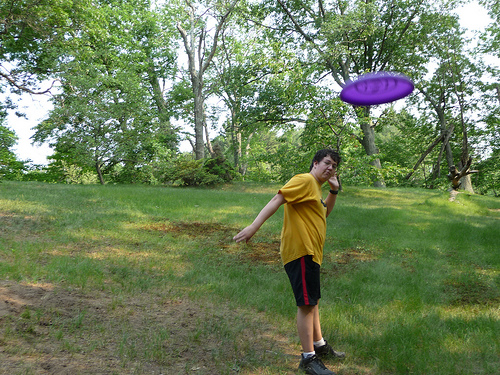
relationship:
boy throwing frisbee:
[229, 149, 348, 374] [339, 75, 418, 106]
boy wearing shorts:
[229, 149, 348, 374] [284, 256, 322, 309]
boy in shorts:
[229, 149, 348, 374] [284, 256, 322, 309]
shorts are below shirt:
[284, 256, 322, 309] [279, 173, 325, 265]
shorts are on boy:
[284, 256, 322, 309] [229, 149, 348, 374]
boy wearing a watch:
[229, 149, 348, 374] [327, 189, 339, 196]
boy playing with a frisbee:
[229, 149, 348, 374] [339, 75, 418, 106]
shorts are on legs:
[284, 256, 322, 309] [295, 265, 325, 358]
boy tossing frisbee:
[229, 149, 348, 374] [339, 75, 418, 106]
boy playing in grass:
[229, 149, 348, 374] [4, 183, 498, 374]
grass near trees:
[4, 183, 498, 374] [2, 0, 498, 198]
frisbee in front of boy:
[339, 75, 418, 106] [229, 149, 348, 374]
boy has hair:
[229, 149, 348, 374] [307, 149, 343, 170]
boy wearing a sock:
[229, 149, 348, 374] [313, 337, 325, 350]